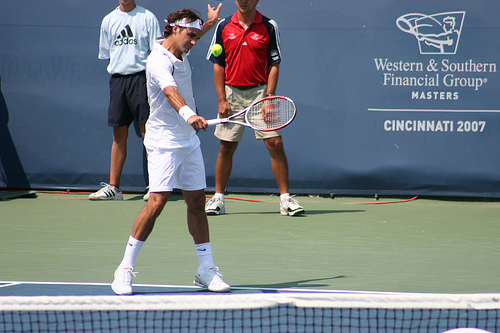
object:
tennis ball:
[211, 44, 223, 57]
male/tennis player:
[110, 2, 231, 297]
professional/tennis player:
[109, 2, 231, 296]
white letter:
[442, 74, 453, 87]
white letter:
[394, 77, 403, 86]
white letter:
[419, 91, 426, 99]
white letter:
[413, 120, 417, 132]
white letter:
[434, 120, 443, 132]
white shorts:
[143, 134, 208, 193]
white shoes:
[110, 266, 231, 297]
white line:
[0, 280, 205, 289]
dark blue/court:
[0, 284, 21, 295]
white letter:
[383, 119, 392, 131]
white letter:
[411, 91, 419, 100]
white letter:
[449, 120, 454, 132]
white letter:
[382, 73, 395, 86]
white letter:
[452, 91, 459, 101]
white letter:
[440, 58, 450, 72]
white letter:
[382, 73, 391, 86]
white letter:
[373, 58, 388, 71]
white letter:
[395, 119, 404, 132]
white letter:
[449, 120, 453, 132]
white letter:
[435, 73, 440, 86]